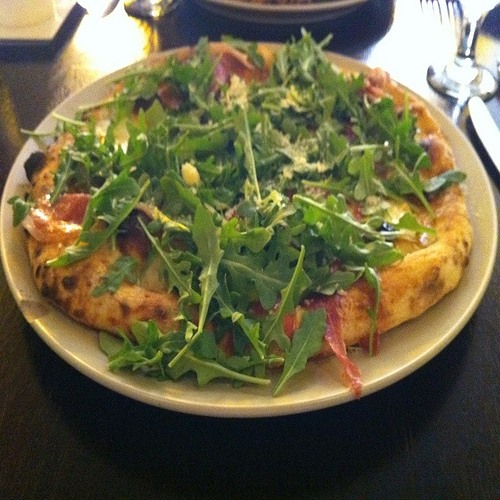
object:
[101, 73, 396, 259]
leaves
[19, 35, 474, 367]
pizza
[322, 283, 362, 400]
bacon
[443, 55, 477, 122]
spoon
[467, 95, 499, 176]
knife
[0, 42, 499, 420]
plate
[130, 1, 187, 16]
glass